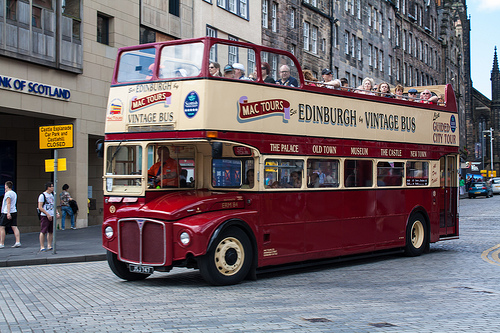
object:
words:
[229, 91, 424, 140]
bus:
[81, 33, 495, 295]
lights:
[173, 225, 197, 251]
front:
[108, 40, 207, 280]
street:
[0, 187, 500, 332]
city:
[1, 0, 499, 333]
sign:
[36, 120, 77, 152]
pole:
[48, 150, 64, 260]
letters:
[34, 123, 78, 150]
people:
[348, 67, 381, 103]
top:
[97, 37, 466, 111]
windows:
[263, 156, 310, 194]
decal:
[181, 89, 202, 119]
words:
[0, 67, 72, 106]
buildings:
[0, 0, 488, 227]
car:
[467, 179, 498, 200]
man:
[34, 177, 61, 254]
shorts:
[34, 212, 61, 237]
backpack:
[32, 190, 48, 219]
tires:
[391, 202, 439, 259]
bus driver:
[147, 141, 186, 191]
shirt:
[146, 159, 186, 188]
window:
[93, 8, 116, 49]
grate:
[111, 215, 169, 271]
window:
[106, 31, 214, 85]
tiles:
[367, 269, 393, 284]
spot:
[300, 311, 332, 326]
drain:
[448, 275, 500, 299]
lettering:
[287, 96, 424, 136]